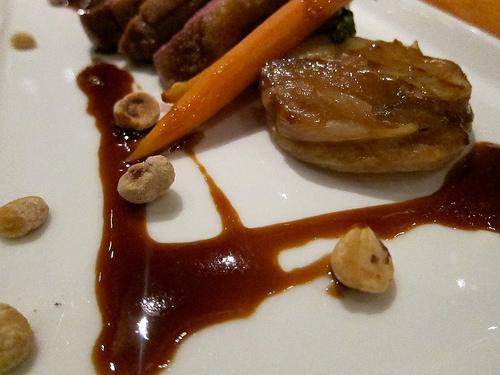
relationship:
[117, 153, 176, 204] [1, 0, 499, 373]
peanut on plate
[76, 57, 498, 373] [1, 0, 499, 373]
sauce on plate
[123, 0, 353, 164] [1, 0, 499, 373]
carrot on plate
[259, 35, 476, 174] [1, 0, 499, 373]
pastry on plate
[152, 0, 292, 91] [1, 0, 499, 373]
meat on plate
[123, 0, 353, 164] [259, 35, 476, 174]
carrot by pastry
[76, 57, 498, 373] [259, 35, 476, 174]
sauce around pastry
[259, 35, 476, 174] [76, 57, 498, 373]
pastry by sauce